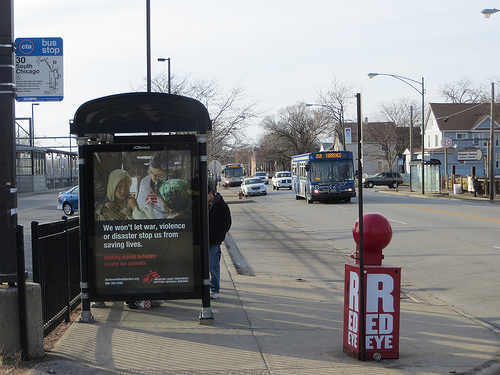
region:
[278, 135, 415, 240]
The bus is on the street.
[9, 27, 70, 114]
The sign is rectangular.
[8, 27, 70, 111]
The sign is for the bus stop.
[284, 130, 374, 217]
The bus has its headlights on.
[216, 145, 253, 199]
The bus has its headlights on.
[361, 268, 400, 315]
The letter is white.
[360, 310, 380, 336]
The letter is white.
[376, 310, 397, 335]
The letter is white.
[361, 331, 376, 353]
The letter is white.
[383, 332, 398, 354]
The letter is white.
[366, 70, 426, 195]
A tall light pole.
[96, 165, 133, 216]
A person on a sign.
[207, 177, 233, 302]
A person wearing a black jacket.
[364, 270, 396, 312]
A white letter R.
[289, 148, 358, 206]
A bus on the street.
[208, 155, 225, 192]
The back of a stop sign.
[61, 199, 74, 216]
The tire on a blue car.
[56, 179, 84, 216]
A parked blue car.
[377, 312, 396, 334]
A white letter D.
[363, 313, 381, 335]
A white letter E.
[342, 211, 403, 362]
Red post with white writing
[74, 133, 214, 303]
Black poster with white and red writing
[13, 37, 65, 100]
Blue and white bus stop sign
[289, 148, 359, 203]
Blue bus driving on road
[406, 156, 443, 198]
Bus stop on side of road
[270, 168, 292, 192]
White truck driving on road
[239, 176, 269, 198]
Car driving on road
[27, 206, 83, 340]
Fence behind bus stop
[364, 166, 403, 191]
SUV driving on road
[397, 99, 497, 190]
Light blue house nearby road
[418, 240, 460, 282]
Part of the street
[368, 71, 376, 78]
Part of the streetlight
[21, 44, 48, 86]
Part of the sign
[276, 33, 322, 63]
Part of the sky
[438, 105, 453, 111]
Part of the building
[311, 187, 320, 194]
The right headlight of the bus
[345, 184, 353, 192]
The left headlight of the bus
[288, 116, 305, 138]
Part of the tree in distance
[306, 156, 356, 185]
A window on the bus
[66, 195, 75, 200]
Part of the blue car